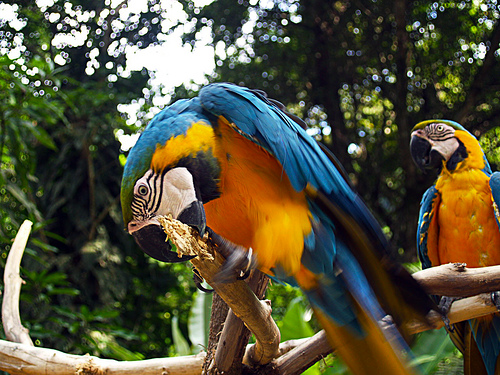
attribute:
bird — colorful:
[394, 114, 499, 285]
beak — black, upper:
[136, 228, 168, 261]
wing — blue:
[414, 187, 441, 269]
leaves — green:
[0, 1, 498, 361]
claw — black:
[109, 73, 431, 368]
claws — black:
[432, 290, 499, 318]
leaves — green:
[341, 10, 459, 68]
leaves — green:
[327, 11, 461, 93]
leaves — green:
[438, 78, 463, 96]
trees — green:
[288, 1, 498, 109]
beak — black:
[135, 205, 209, 266]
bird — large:
[127, 77, 424, 370]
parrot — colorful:
[78, 96, 490, 373]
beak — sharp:
[108, 199, 211, 259]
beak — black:
[179, 192, 226, 233]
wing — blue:
[185, 74, 356, 198]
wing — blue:
[195, 77, 373, 207]